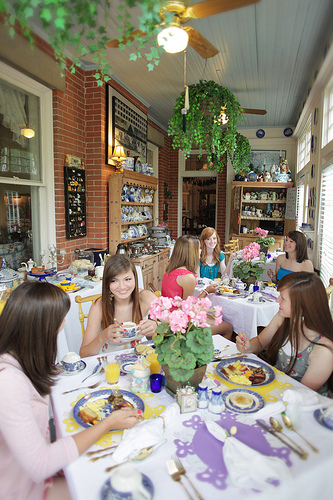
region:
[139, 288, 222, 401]
pot of geraniums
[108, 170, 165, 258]
shelf with dishes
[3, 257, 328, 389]
three ladies eating lunch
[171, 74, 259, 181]
vine hanging from ceiling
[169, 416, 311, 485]
silverware setting laying on table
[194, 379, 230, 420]
salt and pepper shakers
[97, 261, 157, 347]
lady holding cup of tea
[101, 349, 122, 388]
full glass of orange juice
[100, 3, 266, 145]
ceiling fans on ceiling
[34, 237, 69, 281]
silver candelabra on table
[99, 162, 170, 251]
curio cabinet with a lot of beautiful glass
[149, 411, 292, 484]
butterflies on purple place mats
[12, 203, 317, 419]
girls having lunch together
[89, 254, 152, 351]
smiling girl with long brown hair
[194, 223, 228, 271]
smiling girl with long red hair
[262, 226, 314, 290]
girl in blue tube top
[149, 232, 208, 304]
girl in frilly red tank top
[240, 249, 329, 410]
smiling girl in grey tank top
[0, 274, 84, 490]
girl with pink long sleeved shirt on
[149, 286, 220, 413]
pink flowers at table center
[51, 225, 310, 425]
six girls are having breakfast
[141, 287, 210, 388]
pink geraniums are the centerpiece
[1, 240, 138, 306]
breakfast buffet is behind the girls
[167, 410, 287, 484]
place mat with purple decoration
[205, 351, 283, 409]
place mat with yellow decoration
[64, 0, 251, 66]
hanging plant near overhead light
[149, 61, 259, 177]
hanging plant covers overhead light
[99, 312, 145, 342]
girl holding tea of coffee in cup and saucer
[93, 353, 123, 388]
glass of orange juice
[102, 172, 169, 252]
ceramic dishes on display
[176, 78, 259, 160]
A green plant hanging from the ceiling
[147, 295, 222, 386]
Pink flowers in the center of the table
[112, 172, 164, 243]
Dishes line the shelves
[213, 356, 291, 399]
The blue rimmed plate contrasts with the yellow place mat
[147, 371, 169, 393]
A candle sits in a blue holder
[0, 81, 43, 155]
A white lace curtain in the window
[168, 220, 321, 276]
Three women share a table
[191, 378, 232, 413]
Blue and white salt and pepper shakers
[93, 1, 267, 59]
A fan with a bright light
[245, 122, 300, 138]
Blue plates border the top of the wall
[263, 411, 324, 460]
2 gold spoons on the table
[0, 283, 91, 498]
a girl wearing a pink sweater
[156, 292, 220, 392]
a vase of pink flowers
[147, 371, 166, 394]
a blue candle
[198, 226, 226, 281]
a girl wearing a blue top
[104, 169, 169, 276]
a wooden cabinet buffet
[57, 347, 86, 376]
an upside down teacup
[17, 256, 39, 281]
a white glass pitcher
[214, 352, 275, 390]
a plate of breakfast food